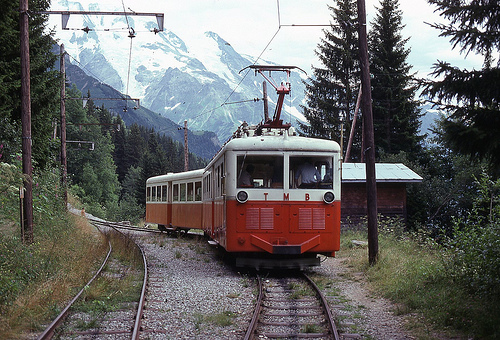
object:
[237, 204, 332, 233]
vents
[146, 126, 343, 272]
car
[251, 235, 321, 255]
bumper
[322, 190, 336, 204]
headlights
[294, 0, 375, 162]
pine tree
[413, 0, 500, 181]
pine tree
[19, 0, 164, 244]
electrical pole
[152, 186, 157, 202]
window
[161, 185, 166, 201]
window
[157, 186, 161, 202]
window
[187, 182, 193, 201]
window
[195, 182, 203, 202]
window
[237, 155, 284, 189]
window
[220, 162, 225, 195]
window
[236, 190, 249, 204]
headlight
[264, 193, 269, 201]
letter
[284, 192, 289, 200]
letter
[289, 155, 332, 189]
window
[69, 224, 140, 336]
weeds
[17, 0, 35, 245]
poles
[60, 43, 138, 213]
electrical wires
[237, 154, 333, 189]
train windshield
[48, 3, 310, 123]
snow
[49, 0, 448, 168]
mountains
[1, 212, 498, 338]
ground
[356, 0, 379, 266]
pole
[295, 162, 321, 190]
conductor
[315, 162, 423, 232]
building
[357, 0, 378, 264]
post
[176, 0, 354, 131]
cable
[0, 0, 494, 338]
countryside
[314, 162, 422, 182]
roof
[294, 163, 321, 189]
man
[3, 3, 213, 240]
fir trees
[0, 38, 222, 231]
hillside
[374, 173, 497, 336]
bushes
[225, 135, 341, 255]
front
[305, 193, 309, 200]
letters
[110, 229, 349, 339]
rocks